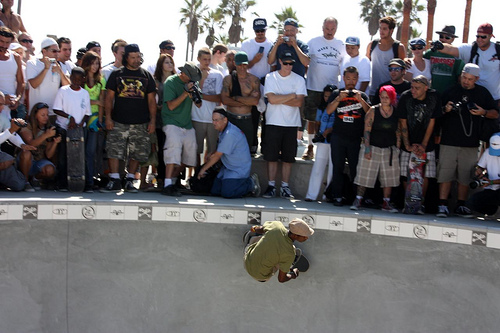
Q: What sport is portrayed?
A: Skateboarding.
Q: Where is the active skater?
A: In the bowl.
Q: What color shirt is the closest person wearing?
A: Green.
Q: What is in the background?
A: Trees.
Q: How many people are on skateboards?
A: 1.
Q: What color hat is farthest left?
A: White.